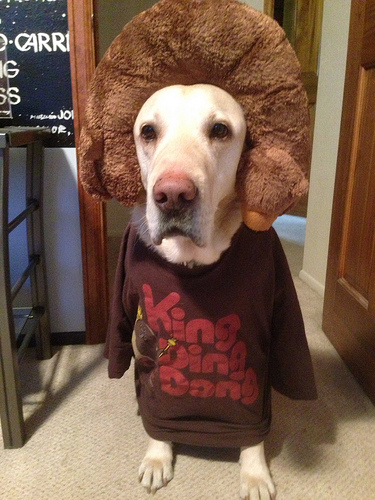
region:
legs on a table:
[0, 128, 52, 448]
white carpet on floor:
[1, 216, 374, 498]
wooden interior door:
[320, 1, 373, 407]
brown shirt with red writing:
[102, 222, 318, 442]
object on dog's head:
[73, 0, 311, 231]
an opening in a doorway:
[95, 0, 351, 343]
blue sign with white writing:
[0, 0, 73, 149]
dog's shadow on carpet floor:
[164, 344, 368, 473]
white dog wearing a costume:
[79, 1, 318, 497]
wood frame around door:
[67, 0, 110, 343]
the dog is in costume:
[65, 8, 314, 485]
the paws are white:
[121, 433, 290, 497]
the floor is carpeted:
[39, 400, 129, 486]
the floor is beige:
[41, 415, 142, 490]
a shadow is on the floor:
[250, 340, 363, 474]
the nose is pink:
[140, 167, 209, 218]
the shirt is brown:
[79, 234, 330, 464]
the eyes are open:
[108, 99, 247, 156]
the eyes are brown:
[103, 95, 241, 154]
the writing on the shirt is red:
[110, 278, 253, 415]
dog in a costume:
[19, 3, 341, 469]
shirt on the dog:
[87, 220, 323, 449]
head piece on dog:
[53, 5, 308, 223]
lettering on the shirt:
[139, 285, 263, 410]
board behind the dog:
[2, 28, 89, 145]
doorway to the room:
[88, 5, 325, 342]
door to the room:
[336, 2, 371, 386]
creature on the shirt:
[129, 314, 183, 399]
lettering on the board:
[1, 23, 72, 131]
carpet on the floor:
[35, 367, 374, 486]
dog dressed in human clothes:
[77, 0, 319, 495]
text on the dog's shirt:
[129, 286, 262, 412]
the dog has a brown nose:
[152, 176, 195, 217]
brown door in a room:
[322, 0, 374, 414]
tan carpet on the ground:
[6, 233, 370, 497]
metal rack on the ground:
[0, 125, 53, 446]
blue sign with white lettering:
[1, 0, 77, 146]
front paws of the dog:
[136, 440, 272, 499]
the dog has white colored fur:
[128, 86, 247, 270]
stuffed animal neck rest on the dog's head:
[76, 0, 306, 229]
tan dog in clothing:
[112, 86, 300, 499]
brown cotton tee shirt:
[106, 221, 319, 450]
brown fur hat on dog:
[76, 3, 309, 219]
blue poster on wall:
[0, 2, 77, 146]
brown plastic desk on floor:
[1, 127, 53, 445]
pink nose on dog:
[153, 175, 196, 208]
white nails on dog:
[145, 488, 156, 497]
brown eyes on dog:
[210, 124, 226, 139]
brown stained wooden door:
[322, 0, 374, 411]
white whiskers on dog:
[134, 211, 162, 239]